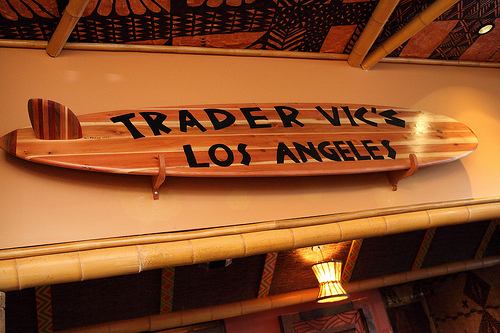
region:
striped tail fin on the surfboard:
[24, 98, 80, 139]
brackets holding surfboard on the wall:
[145, 157, 423, 199]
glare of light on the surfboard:
[406, 111, 433, 160]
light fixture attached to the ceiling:
[308, 258, 350, 306]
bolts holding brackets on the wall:
[154, 184, 400, 198]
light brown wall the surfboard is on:
[4, 51, 494, 242]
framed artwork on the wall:
[274, 298, 378, 331]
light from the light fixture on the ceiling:
[300, 238, 345, 268]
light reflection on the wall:
[421, 76, 498, 198]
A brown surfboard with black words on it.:
[0, 97, 481, 175]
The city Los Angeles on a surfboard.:
[179, 139, 396, 167]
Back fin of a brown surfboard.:
[28, 97, 82, 142]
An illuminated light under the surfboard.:
[311, 258, 348, 305]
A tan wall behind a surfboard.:
[1, 40, 496, 256]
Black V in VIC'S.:
[313, 104, 341, 127]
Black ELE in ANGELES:
[331, 137, 383, 161]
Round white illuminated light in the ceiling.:
[476, 22, 493, 34]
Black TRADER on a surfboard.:
[109, 105, 304, 138]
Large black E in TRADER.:
[240, 105, 273, 129]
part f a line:
[221, 228, 244, 257]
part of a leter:
[235, 105, 265, 223]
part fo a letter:
[278, 145, 308, 205]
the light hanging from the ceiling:
[311, 245, 348, 303]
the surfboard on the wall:
[0, 98, 479, 173]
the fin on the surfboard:
[26, 96, 81, 138]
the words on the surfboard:
[110, 105, 405, 166]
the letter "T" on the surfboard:
[109, 111, 145, 138]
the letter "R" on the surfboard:
[138, 110, 171, 135]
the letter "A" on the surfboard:
[178, 108, 205, 130]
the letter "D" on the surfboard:
[203, 107, 235, 129]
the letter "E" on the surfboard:
[238, 106, 271, 128]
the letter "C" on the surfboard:
[352, 105, 377, 125]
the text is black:
[112, 101, 403, 167]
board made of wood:
[10, 89, 474, 176]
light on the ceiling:
[313, 260, 348, 303]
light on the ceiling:
[475, 19, 488, 34]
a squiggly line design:
[258, 249, 278, 299]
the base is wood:
[150, 153, 165, 196]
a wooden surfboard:
[4, 79, 485, 211]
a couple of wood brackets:
[141, 142, 426, 206]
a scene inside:
[7, 5, 479, 331]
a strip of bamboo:
[1, 197, 499, 295]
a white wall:
[4, 47, 497, 227]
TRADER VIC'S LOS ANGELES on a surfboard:
[98, 90, 417, 185]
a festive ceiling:
[3, 3, 498, 73]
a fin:
[14, 87, 96, 152]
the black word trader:
[110, 97, 306, 132]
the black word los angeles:
[182, 137, 397, 167]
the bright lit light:
[312, 260, 349, 303]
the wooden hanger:
[149, 153, 169, 200]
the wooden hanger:
[388, 153, 419, 192]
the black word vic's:
[315, 100, 409, 127]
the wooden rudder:
[25, 95, 86, 139]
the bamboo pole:
[43, 1, 87, 55]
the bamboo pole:
[346, 0, 396, 64]